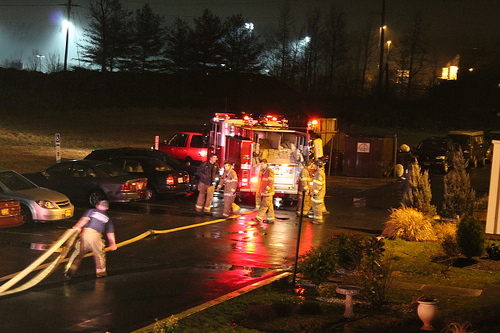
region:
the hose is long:
[4, 205, 264, 295]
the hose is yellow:
[1, 197, 258, 304]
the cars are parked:
[1, 137, 196, 233]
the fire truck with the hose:
[195, 109, 327, 214]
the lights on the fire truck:
[201, 110, 328, 140]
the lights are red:
[243, 110, 318, 132]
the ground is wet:
[158, 220, 288, 278]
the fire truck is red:
[203, 108, 340, 224]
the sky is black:
[443, 10, 476, 33]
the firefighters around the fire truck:
[195, 148, 357, 220]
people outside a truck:
[171, 141, 330, 206]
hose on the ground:
[137, 213, 205, 253]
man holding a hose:
[55, 188, 135, 285]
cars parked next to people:
[81, 139, 181, 216]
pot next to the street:
[407, 281, 441, 331]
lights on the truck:
[251, 106, 289, 141]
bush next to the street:
[445, 211, 487, 258]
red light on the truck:
[235, 106, 262, 132]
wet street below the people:
[145, 244, 216, 292]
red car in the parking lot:
[166, 131, 205, 164]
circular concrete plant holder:
[413, 294, 439, 329]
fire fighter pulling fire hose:
[63, 197, 118, 282]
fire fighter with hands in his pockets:
[196, 152, 221, 216]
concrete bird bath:
[333, 282, 358, 322]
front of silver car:
[1, 166, 76, 221]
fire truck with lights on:
[206, 109, 311, 208]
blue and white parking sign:
[53, 131, 63, 162]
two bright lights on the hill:
[438, 63, 458, 82]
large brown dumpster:
[335, 131, 393, 176]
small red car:
[151, 128, 209, 169]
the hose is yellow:
[43, 247, 55, 274]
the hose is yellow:
[39, 257, 55, 273]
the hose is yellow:
[27, 256, 47, 284]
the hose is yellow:
[49, 248, 64, 273]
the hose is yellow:
[20, 254, 60, 304]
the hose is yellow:
[11, 263, 44, 291]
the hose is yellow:
[9, 266, 64, 313]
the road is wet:
[190, 235, 301, 319]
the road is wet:
[215, 240, 255, 297]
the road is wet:
[143, 177, 225, 268]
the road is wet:
[185, 255, 253, 317]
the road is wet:
[196, 188, 274, 266]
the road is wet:
[146, 171, 276, 289]